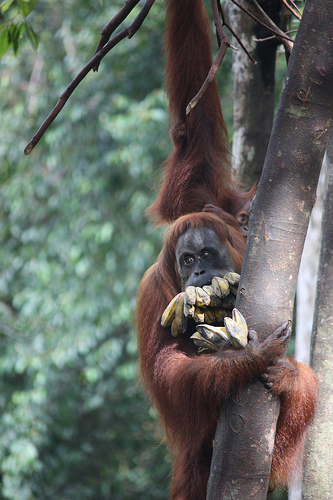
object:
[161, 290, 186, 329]
bananas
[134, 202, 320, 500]
orangutan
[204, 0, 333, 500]
tree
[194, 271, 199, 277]
nostril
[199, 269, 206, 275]
nostril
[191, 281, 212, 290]
mouth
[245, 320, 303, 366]
hand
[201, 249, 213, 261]
eye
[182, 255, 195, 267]
eye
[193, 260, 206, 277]
nose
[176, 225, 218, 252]
forehead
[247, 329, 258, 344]
thumb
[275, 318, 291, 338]
finger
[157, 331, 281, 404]
arm